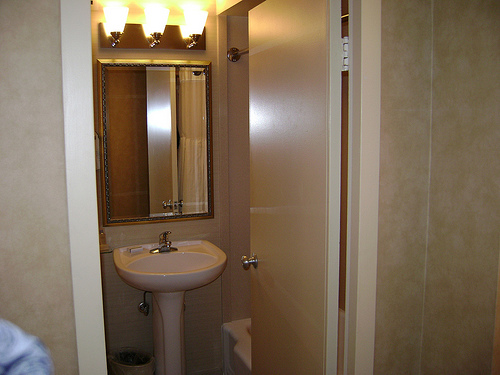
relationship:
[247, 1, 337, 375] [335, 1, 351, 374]
door has a gap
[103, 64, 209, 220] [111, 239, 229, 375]
mirror over sink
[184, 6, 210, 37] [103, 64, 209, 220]
light above mirror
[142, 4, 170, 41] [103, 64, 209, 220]
light above mirror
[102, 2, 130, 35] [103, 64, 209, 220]
light above mirror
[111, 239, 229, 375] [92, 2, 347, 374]
sink in bathroom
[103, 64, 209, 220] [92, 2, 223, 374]
mirror hanging on wall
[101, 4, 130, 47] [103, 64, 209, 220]
light are above mirror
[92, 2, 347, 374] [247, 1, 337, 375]
bathroom has a door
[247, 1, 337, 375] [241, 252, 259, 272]
door has a door knob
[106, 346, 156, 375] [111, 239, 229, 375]
wastebasket underneath sink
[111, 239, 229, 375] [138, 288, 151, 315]
sink has plumbing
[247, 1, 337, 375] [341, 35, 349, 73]
door has a hinge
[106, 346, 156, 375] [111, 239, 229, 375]
wastebasket standing next to sink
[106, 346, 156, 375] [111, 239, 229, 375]
wastebasket beside sink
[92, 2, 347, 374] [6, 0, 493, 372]
bathroom in scene